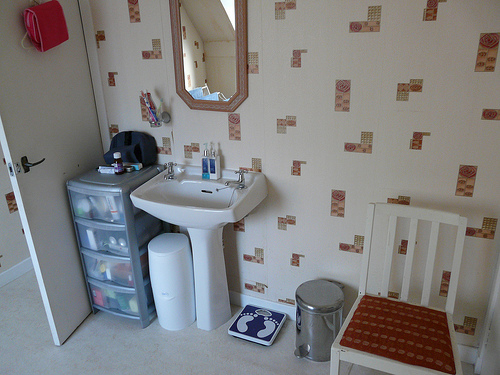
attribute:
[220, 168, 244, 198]
faucet — silver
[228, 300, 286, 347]
scale — blue and white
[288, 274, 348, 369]
trash can — small, metal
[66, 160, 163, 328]
cabinet — gray, plastic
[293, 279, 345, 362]
garbage can — small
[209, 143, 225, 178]
bottle — pump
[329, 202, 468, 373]
white chair — empty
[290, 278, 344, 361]
can — silver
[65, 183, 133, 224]
drawer — plastic, large, square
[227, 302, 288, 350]
scale — blue, white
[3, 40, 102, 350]
door — white, open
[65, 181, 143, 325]
drawer — large, square, plastic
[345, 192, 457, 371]
chair — red and white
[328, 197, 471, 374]
chair — white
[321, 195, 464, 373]
chair — white 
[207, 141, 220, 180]
soap — small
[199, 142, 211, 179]
soap — small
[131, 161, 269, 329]
sink — white, bathroom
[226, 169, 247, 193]
faucet — silver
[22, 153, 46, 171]
door handle — metal